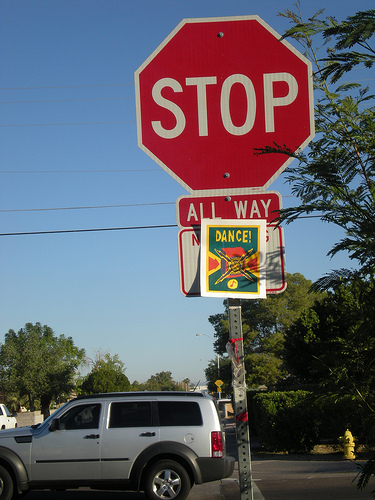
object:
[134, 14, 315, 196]
sign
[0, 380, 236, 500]
car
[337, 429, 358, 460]
fire hydrant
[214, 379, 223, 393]
traffic sign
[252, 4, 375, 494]
tree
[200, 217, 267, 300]
flyer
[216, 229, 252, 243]
dance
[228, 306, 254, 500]
post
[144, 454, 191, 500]
tire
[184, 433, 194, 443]
gas tank door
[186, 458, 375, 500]
street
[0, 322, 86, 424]
tree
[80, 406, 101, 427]
driver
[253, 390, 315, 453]
shrubbery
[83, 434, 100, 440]
door handle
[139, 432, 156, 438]
door handle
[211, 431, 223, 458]
taillight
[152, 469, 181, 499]
rim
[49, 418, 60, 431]
side mirror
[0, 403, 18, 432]
car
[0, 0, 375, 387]
sky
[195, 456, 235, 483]
bumper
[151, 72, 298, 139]
letter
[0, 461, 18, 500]
partial tire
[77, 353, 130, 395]
tree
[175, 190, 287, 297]
sign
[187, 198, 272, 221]
all way